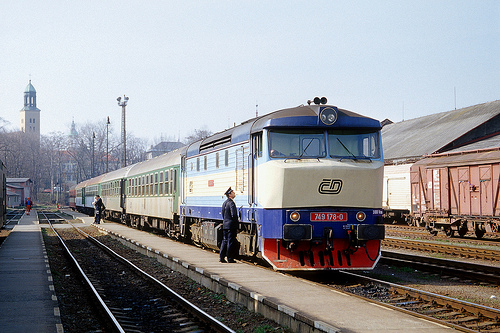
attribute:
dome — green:
[12, 77, 37, 116]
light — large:
[318, 102, 341, 124]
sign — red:
[309, 210, 349, 221]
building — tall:
[1, 73, 46, 165]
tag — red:
[309, 209, 351, 224]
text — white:
[313, 212, 344, 218]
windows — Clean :
[266, 127, 380, 159]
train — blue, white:
[69, 88, 392, 287]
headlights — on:
[288, 208, 365, 223]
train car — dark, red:
[423, 144, 495, 220]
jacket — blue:
[220, 198, 240, 228]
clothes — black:
[220, 197, 238, 253]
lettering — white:
[310, 208, 346, 225]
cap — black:
[222, 185, 234, 195]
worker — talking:
[214, 186, 247, 264]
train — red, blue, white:
[55, 94, 387, 279]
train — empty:
[91, 105, 435, 303]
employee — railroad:
[94, 196, 105, 227]